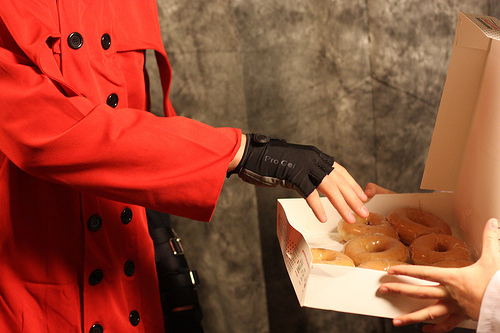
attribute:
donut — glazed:
[342, 229, 412, 264]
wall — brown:
[162, 0, 471, 180]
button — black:
[113, 203, 132, 226]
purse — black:
[120, 189, 249, 330]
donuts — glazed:
[413, 235, 467, 261]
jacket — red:
[1, 5, 245, 331]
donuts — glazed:
[307, 204, 475, 281]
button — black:
[96, 26, 118, 52]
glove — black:
[262, 139, 384, 200]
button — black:
[62, 26, 86, 52]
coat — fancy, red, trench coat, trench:
[3, 2, 242, 332]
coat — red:
[22, 10, 262, 331]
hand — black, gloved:
[217, 100, 365, 238]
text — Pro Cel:
[258, 150, 301, 174]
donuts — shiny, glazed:
[343, 227, 407, 268]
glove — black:
[234, 126, 340, 194]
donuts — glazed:
[332, 202, 461, 272]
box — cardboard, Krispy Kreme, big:
[274, 10, 484, 314]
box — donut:
[256, 216, 358, 306]